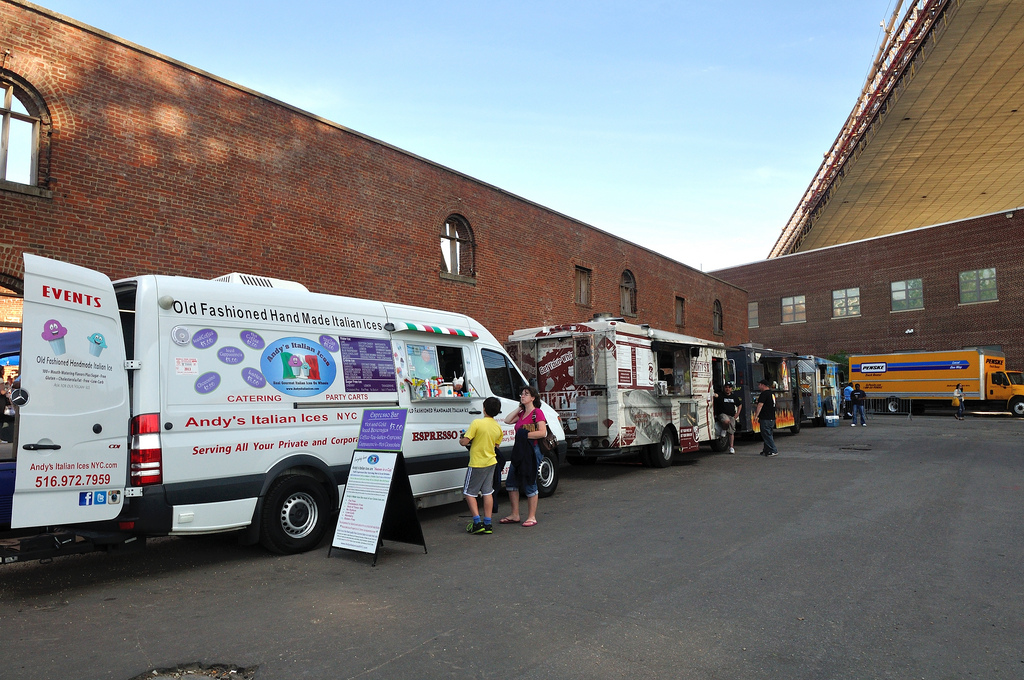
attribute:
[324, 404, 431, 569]
sign — purple, white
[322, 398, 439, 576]
sign — white, purple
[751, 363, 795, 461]
boy — brown haired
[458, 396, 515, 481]
shirt — yellow 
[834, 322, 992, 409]
truck — long orange Penske 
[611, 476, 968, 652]
drive way — long dark grey paved d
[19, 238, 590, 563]
van — long white italian ice , white 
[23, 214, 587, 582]
truck — black food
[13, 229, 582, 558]
word — EVENTS , Red  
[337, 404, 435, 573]
board — white , black 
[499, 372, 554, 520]
woman — pink ,  dark haired 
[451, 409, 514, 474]
t-shirt. — yellow  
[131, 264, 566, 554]
van — food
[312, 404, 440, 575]
board — advertising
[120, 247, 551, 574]
van — food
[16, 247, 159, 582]
door — open, back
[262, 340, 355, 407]
ices — Italian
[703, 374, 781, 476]
person — one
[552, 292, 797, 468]
truck — food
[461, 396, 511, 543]
boy — one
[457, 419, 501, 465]
shirt — yellow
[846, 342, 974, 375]
stripe — blue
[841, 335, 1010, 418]
truck — moving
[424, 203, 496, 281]
window — arched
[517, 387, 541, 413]
hair — female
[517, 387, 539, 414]
face — female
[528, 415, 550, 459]
arm — female, one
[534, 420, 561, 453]
elbow — one, female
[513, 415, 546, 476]
woman — one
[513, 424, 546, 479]
jacket — one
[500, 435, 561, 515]
woman — one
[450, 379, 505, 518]
kid — one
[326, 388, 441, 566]
sign — purple, white